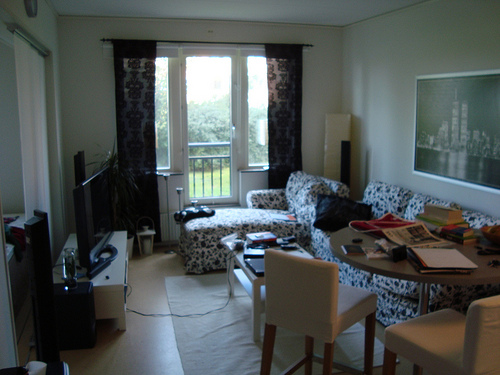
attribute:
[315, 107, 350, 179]
lamp — corner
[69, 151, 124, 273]
screen — large, flat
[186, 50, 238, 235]
door — glass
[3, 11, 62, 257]
window — white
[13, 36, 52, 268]
curtain — open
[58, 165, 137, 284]
tv — flat screen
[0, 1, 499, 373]
living room — ordinary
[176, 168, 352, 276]
chair — floral pattern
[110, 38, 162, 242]
curtains — open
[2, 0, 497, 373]
house — shotgun shack shaped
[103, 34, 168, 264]
curtains — dark, decorative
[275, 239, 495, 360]
chair legs — wooden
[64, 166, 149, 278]
tv — black, flat screen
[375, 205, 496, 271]
books — stacked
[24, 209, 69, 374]
speaker — surround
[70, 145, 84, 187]
speaker — surround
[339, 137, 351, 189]
speaker — surround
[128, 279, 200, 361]
floor — wooden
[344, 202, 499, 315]
table — round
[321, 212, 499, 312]
table — wooden